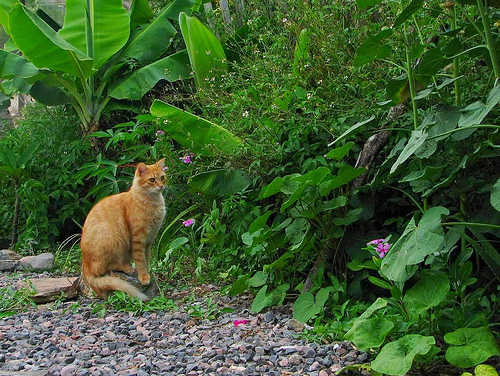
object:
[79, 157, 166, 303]
cat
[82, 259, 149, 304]
tail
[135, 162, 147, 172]
ear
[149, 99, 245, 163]
leaf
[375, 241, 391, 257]
flower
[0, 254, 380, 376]
road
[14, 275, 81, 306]
rock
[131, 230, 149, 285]
leg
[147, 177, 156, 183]
eye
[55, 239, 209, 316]
weed